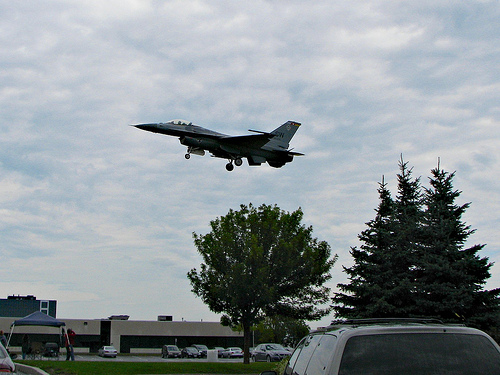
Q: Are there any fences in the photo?
A: No, there are no fences.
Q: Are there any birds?
A: No, there are no birds.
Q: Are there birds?
A: No, there are no birds.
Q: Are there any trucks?
A: No, there are no trucks.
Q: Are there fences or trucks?
A: No, there are no trucks or fences.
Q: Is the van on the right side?
A: Yes, the van is on the right of the image.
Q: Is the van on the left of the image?
A: No, the van is on the right of the image.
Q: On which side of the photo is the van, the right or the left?
A: The van is on the right of the image.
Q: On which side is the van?
A: The van is on the right of the image.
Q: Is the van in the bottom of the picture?
A: Yes, the van is in the bottom of the image.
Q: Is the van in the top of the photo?
A: No, the van is in the bottom of the image.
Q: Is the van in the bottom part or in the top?
A: The van is in the bottom of the image.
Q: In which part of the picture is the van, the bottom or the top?
A: The van is in the bottom of the image.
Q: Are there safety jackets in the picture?
A: No, there are no safety jackets.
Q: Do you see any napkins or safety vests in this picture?
A: No, there are no safety vests or napkins.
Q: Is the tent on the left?
A: Yes, the tent is on the left of the image.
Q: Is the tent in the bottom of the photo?
A: Yes, the tent is in the bottom of the image.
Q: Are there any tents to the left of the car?
A: Yes, there is a tent to the left of the car.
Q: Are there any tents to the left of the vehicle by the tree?
A: Yes, there is a tent to the left of the car.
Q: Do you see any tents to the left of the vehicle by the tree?
A: Yes, there is a tent to the left of the car.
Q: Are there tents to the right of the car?
A: No, the tent is to the left of the car.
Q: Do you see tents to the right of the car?
A: No, the tent is to the left of the car.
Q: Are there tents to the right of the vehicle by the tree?
A: No, the tent is to the left of the car.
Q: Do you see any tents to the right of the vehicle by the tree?
A: No, the tent is to the left of the car.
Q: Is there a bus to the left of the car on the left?
A: No, there is a tent to the left of the car.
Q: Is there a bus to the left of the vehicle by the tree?
A: No, there is a tent to the left of the car.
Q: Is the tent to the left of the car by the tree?
A: Yes, the tent is to the left of the car.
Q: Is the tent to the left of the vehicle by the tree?
A: Yes, the tent is to the left of the car.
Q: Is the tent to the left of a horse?
A: No, the tent is to the left of the car.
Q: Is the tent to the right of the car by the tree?
A: No, the tent is to the left of the car.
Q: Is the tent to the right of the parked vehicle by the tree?
A: No, the tent is to the left of the car.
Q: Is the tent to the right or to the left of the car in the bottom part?
A: The tent is to the left of the car.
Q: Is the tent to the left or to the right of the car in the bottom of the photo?
A: The tent is to the left of the car.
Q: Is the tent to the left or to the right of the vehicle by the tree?
A: The tent is to the left of the car.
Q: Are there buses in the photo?
A: No, there are no buses.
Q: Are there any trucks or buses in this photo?
A: No, there are no buses or trucks.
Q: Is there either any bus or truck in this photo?
A: No, there are no buses or trucks.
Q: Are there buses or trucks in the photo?
A: No, there are no buses or trucks.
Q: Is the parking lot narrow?
A: Yes, the parking lot is narrow.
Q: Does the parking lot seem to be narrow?
A: Yes, the parking lot is narrow.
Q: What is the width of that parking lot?
A: The parking lot is narrow.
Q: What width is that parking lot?
A: The parking lot is narrow.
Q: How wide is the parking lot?
A: The parking lot is narrow.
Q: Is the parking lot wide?
A: No, the parking lot is narrow.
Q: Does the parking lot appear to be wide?
A: No, the parking lot is narrow.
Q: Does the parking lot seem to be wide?
A: No, the parking lot is narrow.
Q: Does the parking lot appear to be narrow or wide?
A: The parking lot is narrow.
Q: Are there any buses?
A: No, there are no buses.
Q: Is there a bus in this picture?
A: No, there are no buses.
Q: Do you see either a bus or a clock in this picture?
A: No, there are no buses or clocks.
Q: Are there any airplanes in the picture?
A: Yes, there is an airplane.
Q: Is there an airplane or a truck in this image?
A: Yes, there is an airplane.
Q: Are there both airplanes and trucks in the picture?
A: No, there is an airplane but no trucks.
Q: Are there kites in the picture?
A: No, there are no kites.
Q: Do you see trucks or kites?
A: No, there are no kites or trucks.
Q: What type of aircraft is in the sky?
A: The aircraft is an airplane.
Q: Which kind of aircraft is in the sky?
A: The aircraft is an airplane.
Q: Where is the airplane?
A: The airplane is in the sky.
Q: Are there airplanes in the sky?
A: Yes, there is an airplane in the sky.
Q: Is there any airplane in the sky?
A: Yes, there is an airplane in the sky.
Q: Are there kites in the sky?
A: No, there is an airplane in the sky.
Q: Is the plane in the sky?
A: Yes, the plane is in the sky.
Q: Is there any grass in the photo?
A: Yes, there is grass.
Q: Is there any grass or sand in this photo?
A: Yes, there is grass.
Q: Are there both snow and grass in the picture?
A: No, there is grass but no snow.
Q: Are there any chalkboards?
A: No, there are no chalkboards.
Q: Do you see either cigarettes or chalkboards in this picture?
A: No, there are no chalkboards or cigarettes.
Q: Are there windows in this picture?
A: Yes, there is a window.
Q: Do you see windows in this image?
A: Yes, there is a window.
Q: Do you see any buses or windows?
A: Yes, there is a window.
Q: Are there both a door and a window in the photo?
A: No, there is a window but no doors.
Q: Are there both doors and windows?
A: No, there is a window but no doors.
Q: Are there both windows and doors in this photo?
A: No, there is a window but no doors.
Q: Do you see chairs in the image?
A: No, there are no chairs.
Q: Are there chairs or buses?
A: No, there are no chairs or buses.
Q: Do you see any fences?
A: No, there are no fences.